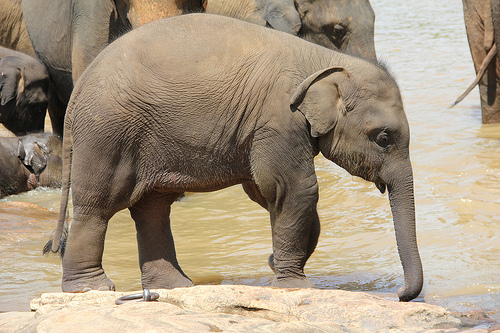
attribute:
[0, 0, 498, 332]
water — brown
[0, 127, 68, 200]
elephant — grey, playing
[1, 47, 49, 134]
elephant — grey, playing, looking down, standing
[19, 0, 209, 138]
elephant — grey, playing, standing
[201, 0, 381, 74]
elephant — grey, playing, standing, looking down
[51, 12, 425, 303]
elephant — grey, playing, standing, looking down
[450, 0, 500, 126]
elephant — standing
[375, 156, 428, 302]
trunk — above water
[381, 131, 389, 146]
eye — round, large, deep-set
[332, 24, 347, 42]
eye — round, large, deep-set